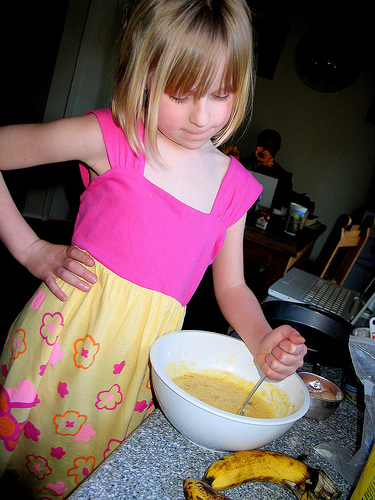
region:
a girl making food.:
[152, 317, 319, 464]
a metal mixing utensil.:
[234, 333, 307, 416]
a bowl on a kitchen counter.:
[303, 359, 352, 416]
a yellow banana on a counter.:
[174, 436, 314, 498]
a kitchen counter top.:
[65, 312, 374, 495]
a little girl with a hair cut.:
[116, 2, 262, 155]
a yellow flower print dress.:
[0, 246, 188, 486]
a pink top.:
[47, 106, 273, 311]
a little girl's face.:
[144, 67, 233, 152]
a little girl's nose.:
[186, 79, 218, 130]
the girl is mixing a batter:
[48, 49, 336, 467]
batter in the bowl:
[184, 363, 272, 419]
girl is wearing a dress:
[55, 58, 257, 424]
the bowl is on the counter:
[156, 298, 352, 493]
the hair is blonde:
[101, 19, 272, 146]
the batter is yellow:
[157, 320, 254, 428]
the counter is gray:
[145, 422, 216, 494]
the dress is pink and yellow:
[49, 99, 193, 432]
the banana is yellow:
[167, 453, 295, 489]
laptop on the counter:
[263, 238, 374, 346]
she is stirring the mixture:
[144, 305, 325, 464]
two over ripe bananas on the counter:
[173, 435, 339, 498]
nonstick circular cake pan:
[241, 276, 364, 375]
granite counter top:
[117, 446, 191, 494]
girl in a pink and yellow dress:
[1, 4, 315, 472]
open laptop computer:
[260, 217, 373, 336]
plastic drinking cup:
[282, 194, 312, 254]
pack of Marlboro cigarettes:
[251, 208, 272, 246]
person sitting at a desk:
[240, 121, 297, 226]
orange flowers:
[222, 138, 279, 174]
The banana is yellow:
[172, 439, 353, 499]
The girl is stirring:
[185, 323, 293, 425]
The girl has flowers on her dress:
[17, 299, 143, 444]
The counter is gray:
[117, 437, 225, 493]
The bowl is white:
[143, 335, 338, 475]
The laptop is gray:
[265, 247, 370, 338]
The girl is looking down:
[140, 56, 240, 141]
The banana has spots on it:
[283, 446, 329, 499]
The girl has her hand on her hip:
[3, 131, 191, 312]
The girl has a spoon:
[249, 340, 304, 423]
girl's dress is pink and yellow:
[48, 94, 261, 299]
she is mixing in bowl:
[139, 294, 294, 457]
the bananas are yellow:
[182, 429, 370, 496]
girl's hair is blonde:
[102, 6, 245, 179]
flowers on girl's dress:
[3, 287, 158, 499]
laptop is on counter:
[262, 219, 364, 341]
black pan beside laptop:
[260, 273, 373, 382]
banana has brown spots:
[147, 441, 373, 495]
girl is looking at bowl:
[133, 48, 286, 147]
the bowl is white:
[115, 296, 307, 472]